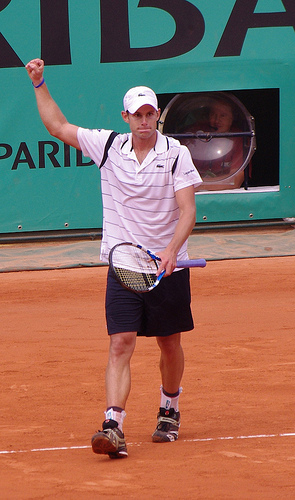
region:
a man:
[78, 142, 258, 466]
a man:
[59, 239, 205, 489]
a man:
[105, 223, 172, 459]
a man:
[119, 286, 191, 476]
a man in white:
[64, 179, 218, 264]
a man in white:
[64, 228, 230, 357]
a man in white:
[65, 31, 192, 263]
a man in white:
[45, 135, 207, 332]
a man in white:
[122, 101, 229, 278]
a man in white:
[74, 186, 165, 311]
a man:
[107, 237, 239, 403]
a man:
[97, 140, 190, 300]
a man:
[126, 166, 212, 482]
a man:
[101, 108, 182, 426]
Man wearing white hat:
[93, 77, 184, 147]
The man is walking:
[47, 70, 236, 481]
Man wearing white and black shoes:
[77, 387, 208, 459]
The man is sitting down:
[149, 80, 261, 183]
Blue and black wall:
[7, 38, 285, 225]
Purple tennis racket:
[108, 212, 208, 290]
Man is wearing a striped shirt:
[82, 84, 204, 265]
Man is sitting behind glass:
[159, 89, 261, 188]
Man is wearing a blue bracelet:
[23, 60, 70, 102]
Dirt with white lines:
[19, 413, 285, 476]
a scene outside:
[1, 0, 289, 499]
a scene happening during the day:
[2, 3, 290, 499]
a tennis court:
[2, 8, 294, 482]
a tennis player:
[23, 55, 205, 460]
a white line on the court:
[1, 428, 293, 453]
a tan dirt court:
[3, 244, 290, 498]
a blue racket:
[100, 232, 221, 299]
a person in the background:
[155, 83, 273, 192]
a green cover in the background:
[1, 0, 293, 243]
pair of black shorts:
[85, 252, 225, 340]